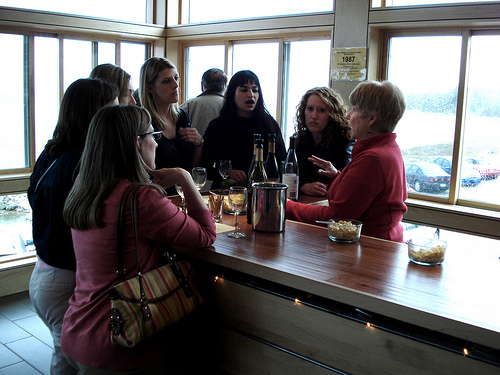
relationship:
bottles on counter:
[237, 120, 320, 220] [79, 144, 499, 355]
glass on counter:
[227, 185, 248, 238] [148, 181, 498, 348]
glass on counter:
[172, 178, 189, 208] [148, 181, 498, 348]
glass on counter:
[190, 162, 207, 191] [148, 181, 498, 348]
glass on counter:
[213, 157, 235, 194] [148, 181, 498, 348]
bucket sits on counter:
[249, 176, 291, 235] [207, 192, 499, 342]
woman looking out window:
[184, 62, 218, 133] [165, 30, 250, 120]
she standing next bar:
[59, 104, 217, 375] [183, 210, 493, 367]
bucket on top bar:
[250, 181, 290, 233] [158, 194, 498, 373]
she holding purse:
[59, 104, 217, 375] [99, 179, 192, 349]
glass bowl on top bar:
[407, 238, 445, 266] [4, 8, 499, 363]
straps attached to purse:
[128, 182, 203, 352] [104, 178, 206, 360]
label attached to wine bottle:
[279, 172, 301, 201] [283, 137, 306, 205]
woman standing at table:
[283, 81, 408, 248] [222, 214, 495, 364]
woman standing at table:
[203, 57, 292, 198] [214, 206, 498, 371]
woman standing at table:
[88, 63, 139, 106] [149, 176, 496, 355]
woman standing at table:
[283, 81, 408, 248] [158, 189, 497, 374]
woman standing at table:
[287, 86, 350, 198] [158, 189, 497, 374]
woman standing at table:
[203, 69, 287, 190] [158, 189, 497, 374]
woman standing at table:
[135, 56, 205, 198] [158, 189, 497, 374]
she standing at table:
[59, 104, 217, 375] [158, 189, 497, 374]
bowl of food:
[407, 237, 448, 266] [408, 244, 446, 264]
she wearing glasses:
[59, 104, 217, 375] [137, 126, 163, 144]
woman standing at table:
[296, 78, 406, 225] [180, 212, 497, 333]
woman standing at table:
[203, 69, 287, 190] [178, 185, 498, 353]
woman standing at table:
[131, 57, 205, 197] [173, 180, 479, 372]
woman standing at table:
[283, 81, 408, 248] [180, 212, 497, 333]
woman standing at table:
[278, 86, 351, 210] [180, 212, 497, 333]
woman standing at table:
[203, 69, 287, 190] [180, 212, 497, 333]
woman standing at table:
[131, 57, 205, 197] [180, 212, 497, 333]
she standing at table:
[59, 104, 217, 375] [180, 212, 497, 333]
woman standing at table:
[26, 80, 120, 371] [180, 212, 497, 333]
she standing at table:
[59, 104, 217, 375] [178, 185, 498, 353]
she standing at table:
[59, 104, 217, 375] [198, 196, 485, 366]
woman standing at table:
[92, 62, 135, 104] [282, 216, 464, 339]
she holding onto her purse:
[34, 116, 226, 323] [99, 254, 241, 346]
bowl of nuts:
[404, 237, 447, 267] [411, 247, 443, 266]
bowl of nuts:
[319, 214, 367, 244] [329, 214, 357, 230]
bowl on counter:
[404, 237, 447, 267] [176, 192, 483, 368]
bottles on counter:
[281, 137, 298, 202] [197, 198, 499, 348]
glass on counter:
[223, 183, 250, 245] [176, 190, 498, 336]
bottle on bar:
[248, 140, 272, 222] [241, 134, 271, 196]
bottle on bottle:
[263, 129, 283, 176] [248, 140, 272, 222]